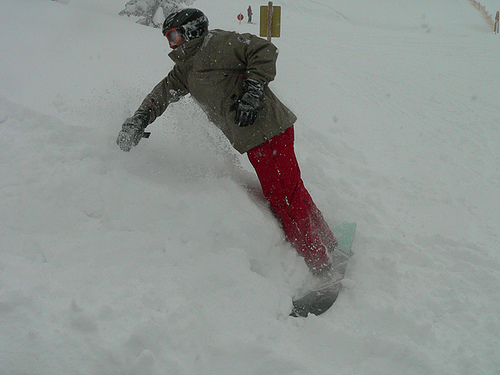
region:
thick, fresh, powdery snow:
[1, 0, 498, 372]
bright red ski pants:
[245, 123, 336, 273]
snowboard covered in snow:
[291, 217, 354, 322]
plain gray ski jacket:
[124, 27, 297, 156]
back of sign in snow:
[258, 2, 280, 41]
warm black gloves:
[114, 79, 264, 151]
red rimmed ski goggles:
[161, 25, 186, 45]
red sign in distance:
[235, 12, 244, 24]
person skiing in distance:
[245, 5, 255, 22]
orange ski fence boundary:
[469, 0, 499, 30]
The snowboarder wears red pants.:
[225, 115, 352, 276]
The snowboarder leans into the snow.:
[101, 2, 365, 341]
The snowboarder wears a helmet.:
[155, 6, 213, 63]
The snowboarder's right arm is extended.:
[105, 56, 184, 168]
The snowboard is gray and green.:
[282, 205, 361, 327]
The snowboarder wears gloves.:
[229, 66, 277, 131]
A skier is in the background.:
[237, 2, 259, 28]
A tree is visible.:
[117, 0, 200, 35]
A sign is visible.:
[249, 1, 295, 49]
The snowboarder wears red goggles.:
[159, 24, 188, 51]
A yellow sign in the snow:
[254, 2, 294, 43]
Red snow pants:
[242, 113, 372, 300]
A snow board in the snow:
[272, 206, 373, 343]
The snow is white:
[10, 153, 268, 371]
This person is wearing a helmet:
[154, 1, 214, 75]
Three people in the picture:
[115, 2, 373, 330]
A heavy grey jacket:
[137, 21, 294, 193]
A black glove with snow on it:
[224, 72, 274, 132]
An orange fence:
[465, 1, 497, 45]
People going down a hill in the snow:
[5, 8, 492, 372]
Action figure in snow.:
[117, 12, 372, 324]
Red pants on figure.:
[247, 132, 342, 278]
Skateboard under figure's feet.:
[296, 200, 370, 333]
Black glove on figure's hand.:
[239, 72, 261, 123]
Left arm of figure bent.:
[215, 33, 301, 132]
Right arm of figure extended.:
[112, 80, 204, 177]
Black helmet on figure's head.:
[158, 6, 217, 52]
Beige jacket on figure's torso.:
[113, 30, 304, 152]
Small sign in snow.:
[262, 2, 284, 41]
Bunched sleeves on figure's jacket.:
[143, 35, 275, 117]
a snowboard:
[292, 220, 365, 320]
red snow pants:
[244, 124, 355, 279]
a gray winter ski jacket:
[129, 27, 311, 152]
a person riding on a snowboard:
[113, 10, 361, 327]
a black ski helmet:
[162, 6, 212, 45]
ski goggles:
[163, 25, 182, 47]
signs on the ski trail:
[233, 3, 285, 40]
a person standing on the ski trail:
[246, 6, 254, 31]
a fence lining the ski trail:
[463, 2, 498, 41]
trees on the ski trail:
[118, 0, 200, 32]